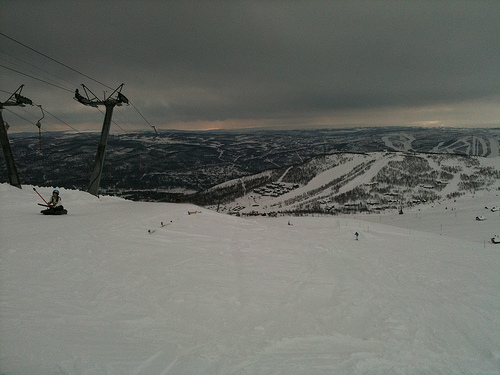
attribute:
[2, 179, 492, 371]
snow — thick, white, fresh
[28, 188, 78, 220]
person — skiing, up close, wearing, sitting, falling, going down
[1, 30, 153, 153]
lines — going down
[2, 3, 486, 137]
clouds — stormy, gray, dark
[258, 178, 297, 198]
cars — parked, covered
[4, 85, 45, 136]
ski lift — snowy, for skiing, present, metal, in the air, posted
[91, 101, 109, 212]
pole — holding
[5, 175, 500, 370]
mountain — snowy, present, snow covered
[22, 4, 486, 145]
sky — blue gray, gray, cloudy, pink